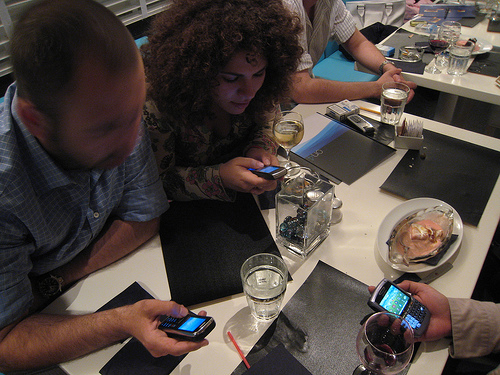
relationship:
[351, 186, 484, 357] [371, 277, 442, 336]
person holding cellphone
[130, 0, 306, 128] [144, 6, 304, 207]
hair of girl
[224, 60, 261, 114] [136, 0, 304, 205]
face of woman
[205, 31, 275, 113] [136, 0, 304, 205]
head of woman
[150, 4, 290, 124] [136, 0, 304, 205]
hair of woman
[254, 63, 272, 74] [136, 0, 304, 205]
eyebrow of woman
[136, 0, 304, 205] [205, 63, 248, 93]
woman has an eye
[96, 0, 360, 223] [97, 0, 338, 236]
woman has lips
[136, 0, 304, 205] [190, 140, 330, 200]
woman has hands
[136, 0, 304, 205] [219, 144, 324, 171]
woman has thumbs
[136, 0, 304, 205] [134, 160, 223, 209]
woman has a sleeve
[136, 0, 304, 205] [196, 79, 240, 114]
woman has a cheek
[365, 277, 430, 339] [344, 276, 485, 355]
phone in palm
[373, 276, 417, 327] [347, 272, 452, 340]
screen on phone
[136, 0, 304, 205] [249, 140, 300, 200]
woman on phone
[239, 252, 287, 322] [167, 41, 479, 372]
glass on end of table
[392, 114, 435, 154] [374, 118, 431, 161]
packets in dish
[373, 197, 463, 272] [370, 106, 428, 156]
plate holding package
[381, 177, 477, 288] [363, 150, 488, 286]
food on plate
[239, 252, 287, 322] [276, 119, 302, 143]
glass with wine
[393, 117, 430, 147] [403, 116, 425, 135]
box with packets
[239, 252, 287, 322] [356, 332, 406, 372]
glass with wine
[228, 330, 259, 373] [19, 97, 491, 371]
straw on table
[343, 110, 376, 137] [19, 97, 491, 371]
cellphone on table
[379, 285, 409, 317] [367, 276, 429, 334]
apps on cellphone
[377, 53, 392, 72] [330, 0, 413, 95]
watch on arm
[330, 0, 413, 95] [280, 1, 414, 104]
arm on man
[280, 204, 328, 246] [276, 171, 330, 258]
marbles in glass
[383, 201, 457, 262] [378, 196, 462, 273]
fish on plate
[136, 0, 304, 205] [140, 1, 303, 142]
woman has hair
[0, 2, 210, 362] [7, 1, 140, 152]
man has hair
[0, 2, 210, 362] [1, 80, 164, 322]
man wearing shirt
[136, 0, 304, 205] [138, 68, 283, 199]
woman wearing jacket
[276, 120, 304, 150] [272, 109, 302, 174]
wine in wine glass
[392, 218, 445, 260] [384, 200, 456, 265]
food in dish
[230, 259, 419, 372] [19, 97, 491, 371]
mat on table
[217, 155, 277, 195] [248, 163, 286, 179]
hand in phone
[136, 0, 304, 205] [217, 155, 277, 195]
woman has hand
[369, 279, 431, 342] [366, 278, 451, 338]
phone in hand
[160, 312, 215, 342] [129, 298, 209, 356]
cell phone in hand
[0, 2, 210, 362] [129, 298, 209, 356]
man has hand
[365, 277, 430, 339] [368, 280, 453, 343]
phone in hand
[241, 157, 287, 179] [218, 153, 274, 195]
cell phone in hand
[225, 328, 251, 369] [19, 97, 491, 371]
straw on table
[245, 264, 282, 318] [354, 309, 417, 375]
water in glass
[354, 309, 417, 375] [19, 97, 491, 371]
glass on table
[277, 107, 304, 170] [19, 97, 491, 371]
wine glass on table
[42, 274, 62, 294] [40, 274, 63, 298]
watch on wrist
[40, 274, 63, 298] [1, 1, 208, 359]
wrist on person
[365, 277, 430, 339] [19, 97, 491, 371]
phone on table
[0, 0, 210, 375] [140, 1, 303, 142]
man has hair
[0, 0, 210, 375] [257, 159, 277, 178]
man holding phone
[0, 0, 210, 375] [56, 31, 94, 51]
man has hair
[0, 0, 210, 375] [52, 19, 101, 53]
man has hair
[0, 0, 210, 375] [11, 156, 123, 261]
man wearing shirt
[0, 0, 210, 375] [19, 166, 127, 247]
man wearing shirt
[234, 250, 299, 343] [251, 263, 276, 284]
glass of water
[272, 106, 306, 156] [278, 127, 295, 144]
glass of wine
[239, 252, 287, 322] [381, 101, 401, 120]
glass of water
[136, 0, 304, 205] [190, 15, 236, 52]
woman has hair